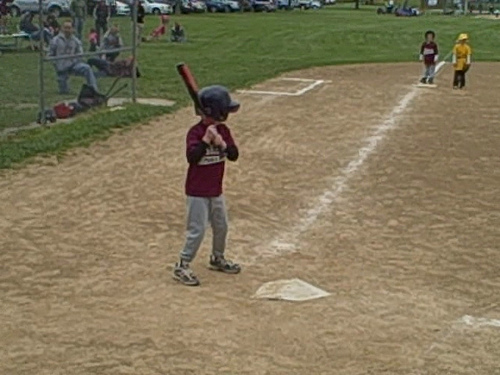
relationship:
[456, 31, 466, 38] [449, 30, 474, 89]
hat on boy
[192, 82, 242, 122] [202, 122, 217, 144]
black in hand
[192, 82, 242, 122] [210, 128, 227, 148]
black in hand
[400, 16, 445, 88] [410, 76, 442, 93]
boy standing on base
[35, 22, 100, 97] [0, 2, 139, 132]
man behind fence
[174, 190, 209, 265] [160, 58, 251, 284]
leg of batter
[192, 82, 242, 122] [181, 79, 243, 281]
black on child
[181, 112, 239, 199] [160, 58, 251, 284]
shirt on batter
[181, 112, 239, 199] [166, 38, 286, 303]
shirt on child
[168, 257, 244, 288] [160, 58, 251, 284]
shoes on batter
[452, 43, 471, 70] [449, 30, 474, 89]
yellow shirt on boy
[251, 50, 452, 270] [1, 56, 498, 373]
line on baseball field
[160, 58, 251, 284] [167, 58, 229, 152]
batter holding bat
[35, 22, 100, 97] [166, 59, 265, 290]
man watching boy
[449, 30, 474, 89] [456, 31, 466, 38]
boy wearing hat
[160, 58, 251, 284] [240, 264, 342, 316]
batter standing at base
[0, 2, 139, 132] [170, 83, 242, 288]
fence behind batter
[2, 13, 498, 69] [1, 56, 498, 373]
grass near baseball field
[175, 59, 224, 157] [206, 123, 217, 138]
baseball in hand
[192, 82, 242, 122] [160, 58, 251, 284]
black on batter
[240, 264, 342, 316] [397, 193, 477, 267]
base covered in dirt